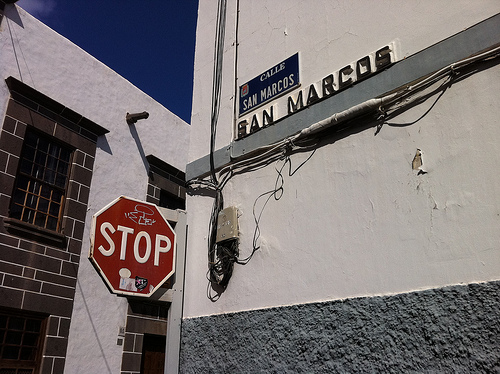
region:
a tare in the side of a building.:
[401, 132, 436, 184]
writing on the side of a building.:
[231, 38, 400, 146]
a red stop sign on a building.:
[90, 196, 178, 297]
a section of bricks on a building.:
[109, 293, 175, 371]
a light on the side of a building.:
[126, 99, 154, 129]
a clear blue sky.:
[17, 0, 197, 126]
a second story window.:
[1, 118, 96, 252]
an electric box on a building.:
[210, 202, 249, 274]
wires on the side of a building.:
[232, 40, 498, 261]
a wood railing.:
[9, 183, 66, 227]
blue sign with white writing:
[238, 52, 300, 118]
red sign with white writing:
[91, 194, 175, 295]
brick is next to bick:
[66, 180, 82, 203]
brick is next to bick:
[58, 214, 77, 239]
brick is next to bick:
[45, 314, 60, 338]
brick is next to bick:
[18, 233, 45, 252]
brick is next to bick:
[44, 239, 69, 259]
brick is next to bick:
[22, 265, 37, 277]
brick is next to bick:
[61, 256, 79, 276]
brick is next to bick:
[3, 113, 19, 135]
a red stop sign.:
[86, 188, 190, 304]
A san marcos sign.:
[229, 40, 412, 145]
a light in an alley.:
[120, 103, 155, 130]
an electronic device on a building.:
[207, 189, 242, 287]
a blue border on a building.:
[186, 17, 495, 182]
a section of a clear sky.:
[24, 0, 198, 122]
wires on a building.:
[233, 45, 495, 268]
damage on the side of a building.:
[404, 136, 424, 202]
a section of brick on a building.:
[0, 70, 113, 371]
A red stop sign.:
[84, 194, 186, 299]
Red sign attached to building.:
[72, 192, 184, 287]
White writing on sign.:
[98, 223, 189, 238]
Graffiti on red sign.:
[115, 204, 176, 217]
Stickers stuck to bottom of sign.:
[117, 263, 175, 298]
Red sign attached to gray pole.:
[89, 180, 211, 289]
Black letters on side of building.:
[234, 37, 453, 96]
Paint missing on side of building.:
[405, 143, 424, 158]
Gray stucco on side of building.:
[219, 315, 429, 369]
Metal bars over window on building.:
[15, 130, 83, 247]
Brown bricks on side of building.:
[18, 247, 85, 302]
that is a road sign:
[95, 182, 186, 299]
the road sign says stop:
[93, 196, 175, 291]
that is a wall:
[286, 312, 340, 344]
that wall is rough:
[297, 320, 424, 365]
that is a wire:
[264, 169, 291, 207]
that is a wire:
[215, 161, 242, 199]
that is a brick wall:
[4, 165, 85, 284]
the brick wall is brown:
[2, 97, 73, 372]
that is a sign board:
[239, 55, 326, 115]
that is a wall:
[299, 199, 345, 261]